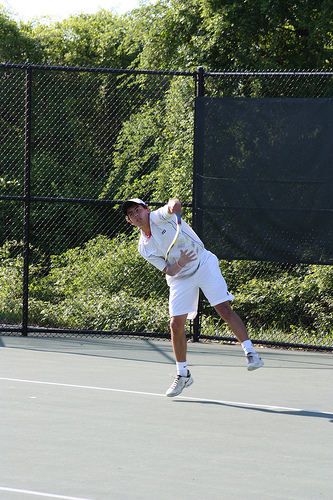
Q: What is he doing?
A: Playing a game.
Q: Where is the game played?
A: On a court.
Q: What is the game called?
A: Tennis.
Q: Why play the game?
A: To get a winner.